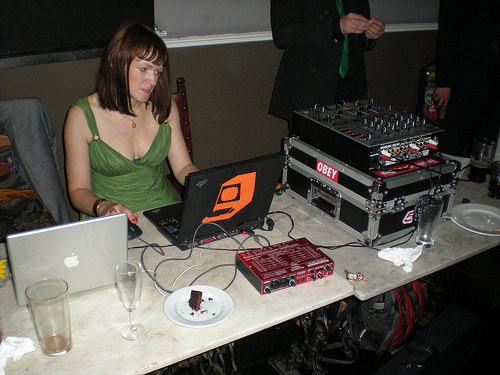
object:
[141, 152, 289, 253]
laptop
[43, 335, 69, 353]
liquid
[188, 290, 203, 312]
cake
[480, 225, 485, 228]
crumbs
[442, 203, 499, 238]
plate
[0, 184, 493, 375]
table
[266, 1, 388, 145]
man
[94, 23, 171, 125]
hair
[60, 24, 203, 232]
woman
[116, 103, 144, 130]
necklace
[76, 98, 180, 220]
dress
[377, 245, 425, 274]
napkin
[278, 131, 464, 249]
case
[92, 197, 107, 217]
bracelet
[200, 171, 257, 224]
orange design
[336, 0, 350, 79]
green neck tie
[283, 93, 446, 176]
electrical device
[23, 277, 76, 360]
clear glass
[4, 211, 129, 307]
apple laptop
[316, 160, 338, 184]
an obey sticker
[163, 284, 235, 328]
white plate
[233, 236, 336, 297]
electronics equipmen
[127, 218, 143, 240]
black mouse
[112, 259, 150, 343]
champagne glass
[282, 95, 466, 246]
audio system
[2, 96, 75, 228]
mens suit jacket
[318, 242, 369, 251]
multiple wires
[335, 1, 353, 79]
wearing a green tie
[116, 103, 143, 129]
wears a necklace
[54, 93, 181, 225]
wears a green dress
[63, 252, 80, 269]
an apple is on the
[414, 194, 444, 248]
glass is empty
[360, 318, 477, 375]
he case is black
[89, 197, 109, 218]
wearing a bracelet